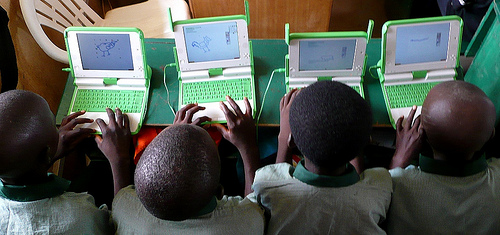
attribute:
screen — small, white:
[183, 20, 240, 64]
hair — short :
[1, 87, 37, 161]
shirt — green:
[1, 174, 114, 234]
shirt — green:
[111, 182, 268, 233]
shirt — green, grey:
[248, 157, 393, 233]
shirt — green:
[391, 151, 499, 233]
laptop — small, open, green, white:
[58, 24, 158, 142]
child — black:
[1, 85, 134, 233]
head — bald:
[415, 76, 498, 175]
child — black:
[254, 80, 391, 230]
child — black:
[5, 79, 149, 229]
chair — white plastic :
[16, 0, 191, 61]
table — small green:
[50, 32, 475, 130]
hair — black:
[289, 82, 369, 159]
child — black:
[374, 75, 499, 232]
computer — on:
[46, 14, 161, 159]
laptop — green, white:
[166, 13, 254, 125]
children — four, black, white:
[2, 82, 498, 229]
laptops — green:
[54, 10, 497, 116]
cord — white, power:
[161, 56, 186, 124]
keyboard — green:
[378, 62, 464, 107]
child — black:
[0, 76, 108, 233]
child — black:
[94, 97, 260, 229]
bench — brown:
[4, 7, 344, 131]